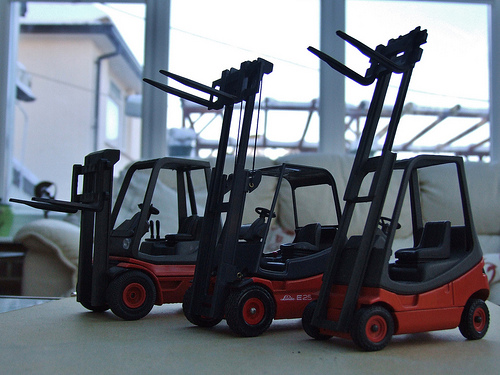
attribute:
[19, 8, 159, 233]
building — cream colored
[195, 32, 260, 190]
lever — black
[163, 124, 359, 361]
lift — fork, steering, black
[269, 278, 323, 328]
bottom — red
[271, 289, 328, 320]
writing — white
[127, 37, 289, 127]
arm — rest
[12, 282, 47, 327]
drain — storm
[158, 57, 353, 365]
fork — lift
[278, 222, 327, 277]
chair — black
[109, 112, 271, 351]
model — red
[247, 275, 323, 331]
decal — white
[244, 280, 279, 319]
wheel — red, black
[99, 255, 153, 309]
tire — black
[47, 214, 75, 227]
slab — concrete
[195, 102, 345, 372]
vehicle — red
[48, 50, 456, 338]
photo — clear, taken